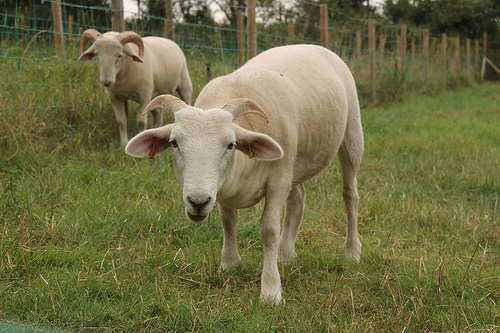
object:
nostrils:
[201, 196, 212, 210]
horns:
[80, 28, 106, 61]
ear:
[231, 122, 284, 162]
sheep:
[75, 27, 193, 149]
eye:
[169, 137, 180, 149]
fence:
[0, 0, 497, 158]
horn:
[219, 97, 270, 124]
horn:
[142, 94, 190, 121]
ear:
[123, 123, 174, 159]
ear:
[123, 43, 144, 63]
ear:
[78, 45, 98, 62]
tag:
[149, 138, 165, 160]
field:
[0, 81, 500, 331]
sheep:
[123, 43, 365, 308]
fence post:
[399, 24, 408, 102]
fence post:
[422, 29, 429, 95]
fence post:
[441, 34, 447, 92]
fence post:
[368, 18, 376, 105]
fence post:
[319, 4, 329, 48]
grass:
[1, 3, 499, 331]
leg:
[337, 119, 364, 262]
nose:
[185, 195, 212, 211]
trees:
[291, 1, 391, 58]